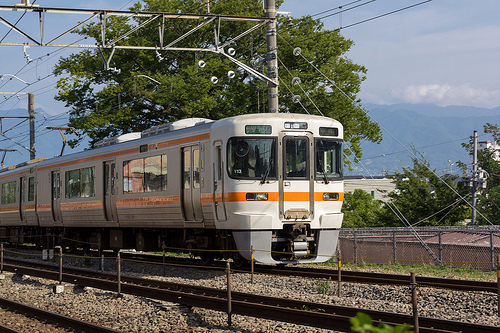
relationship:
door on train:
[276, 127, 315, 224] [7, 110, 354, 270]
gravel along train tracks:
[0, 254, 500, 331] [0, 240, 500, 331]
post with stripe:
[330, 249, 356, 310] [325, 256, 347, 268]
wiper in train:
[321, 140, 336, 187] [7, 110, 354, 270]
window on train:
[105, 135, 195, 235] [17, 74, 358, 295]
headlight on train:
[241, 190, 273, 202] [76, 89, 363, 291]